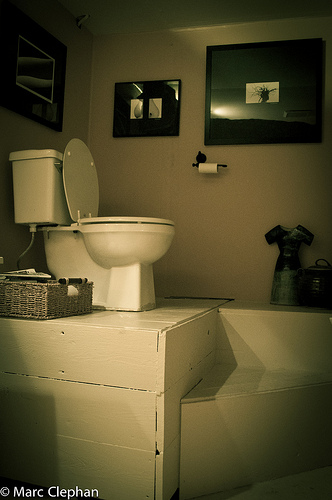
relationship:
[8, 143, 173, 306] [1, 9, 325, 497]
toilet in bathroom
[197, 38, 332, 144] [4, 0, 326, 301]
picture on wall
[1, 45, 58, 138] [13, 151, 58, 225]
pike on tank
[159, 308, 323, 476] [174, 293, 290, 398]
stairs go up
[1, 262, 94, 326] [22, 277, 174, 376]
basket on ground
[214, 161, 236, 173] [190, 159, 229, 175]
handle for towel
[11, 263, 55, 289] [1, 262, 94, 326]
magazine on basket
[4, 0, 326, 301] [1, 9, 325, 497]
wall in bathroom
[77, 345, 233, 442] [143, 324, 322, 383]
wood on riser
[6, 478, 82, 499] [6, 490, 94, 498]
name of photographer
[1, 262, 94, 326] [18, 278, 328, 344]
basket on floor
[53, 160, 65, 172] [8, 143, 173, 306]
lever on toilet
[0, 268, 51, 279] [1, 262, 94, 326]
magazine in basket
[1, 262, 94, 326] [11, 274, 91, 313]
basket of reeds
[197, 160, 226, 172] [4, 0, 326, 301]
tissue on wall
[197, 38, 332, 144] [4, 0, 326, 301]
tv on wall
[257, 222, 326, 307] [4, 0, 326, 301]
dress on wall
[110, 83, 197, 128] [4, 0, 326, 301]
black on wall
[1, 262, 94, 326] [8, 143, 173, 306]
basket by toilet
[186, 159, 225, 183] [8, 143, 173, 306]
roll by toilet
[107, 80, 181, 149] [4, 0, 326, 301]
frame on wall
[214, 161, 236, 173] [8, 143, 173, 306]
handle on toilet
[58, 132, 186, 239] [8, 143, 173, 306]
seat on toilet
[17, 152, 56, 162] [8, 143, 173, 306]
cover on toilet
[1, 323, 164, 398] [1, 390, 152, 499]
part of drawer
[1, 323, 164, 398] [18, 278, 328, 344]
part of floor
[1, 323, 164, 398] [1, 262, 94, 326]
part of basket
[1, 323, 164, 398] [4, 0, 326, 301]
part of wall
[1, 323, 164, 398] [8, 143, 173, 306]
part of toilet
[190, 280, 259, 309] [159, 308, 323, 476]
edge of stairs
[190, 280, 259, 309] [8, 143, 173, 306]
edge of toilet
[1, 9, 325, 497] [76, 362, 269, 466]
scene in a bathroom